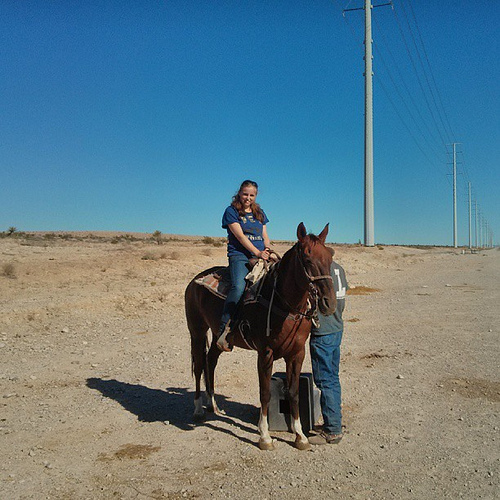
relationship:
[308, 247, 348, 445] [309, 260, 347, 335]
man wearing a shirt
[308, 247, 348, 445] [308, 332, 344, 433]
man wearing jeans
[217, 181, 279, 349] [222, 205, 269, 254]
girl has a t-shirt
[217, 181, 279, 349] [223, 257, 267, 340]
girl wearing jeans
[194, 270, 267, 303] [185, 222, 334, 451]
blanket on horse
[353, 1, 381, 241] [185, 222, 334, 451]
post next to horse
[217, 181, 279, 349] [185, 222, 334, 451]
girl sitting on horse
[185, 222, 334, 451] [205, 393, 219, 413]
horse has white stocking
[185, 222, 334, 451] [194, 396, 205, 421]
horse has white stocking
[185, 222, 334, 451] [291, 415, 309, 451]
horse has white stocking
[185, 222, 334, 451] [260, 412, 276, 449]
horse has white stocking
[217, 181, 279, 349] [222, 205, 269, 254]
girl wearing a tee shirt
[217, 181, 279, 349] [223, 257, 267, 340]
girl wearing a pair of jeans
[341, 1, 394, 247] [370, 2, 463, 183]
post holding up wires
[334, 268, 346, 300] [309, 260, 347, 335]
number one on back of th shirt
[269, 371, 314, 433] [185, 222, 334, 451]
step used to board horse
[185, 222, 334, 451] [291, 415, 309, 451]
horse has white feet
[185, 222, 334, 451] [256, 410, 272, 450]
horse has white feet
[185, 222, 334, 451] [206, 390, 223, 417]
horse has white feet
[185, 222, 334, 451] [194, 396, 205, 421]
horse has white feet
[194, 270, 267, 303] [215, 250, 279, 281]
blanket under saddle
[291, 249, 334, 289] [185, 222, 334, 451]
bridle on horse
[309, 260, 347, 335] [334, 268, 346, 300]
t-shirt has number one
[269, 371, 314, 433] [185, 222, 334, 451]
box used to get on th horse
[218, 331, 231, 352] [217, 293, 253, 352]
rider's foot in stirup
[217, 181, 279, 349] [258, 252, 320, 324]
woman holding reins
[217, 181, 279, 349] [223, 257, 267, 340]
woman wearing jeans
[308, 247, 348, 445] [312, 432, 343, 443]
man wearing cowboy boots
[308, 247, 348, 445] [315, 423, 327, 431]
man wearing cowboy boots